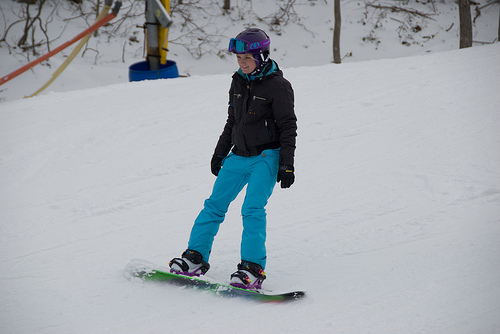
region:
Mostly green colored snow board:
[125, 258, 305, 299]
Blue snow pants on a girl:
[188, 142, 281, 269]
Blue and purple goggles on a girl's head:
[227, 35, 272, 55]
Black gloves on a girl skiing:
[211, 153, 295, 189]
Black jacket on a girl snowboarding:
[215, 63, 298, 168]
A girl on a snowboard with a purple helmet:
[169, 27, 298, 287]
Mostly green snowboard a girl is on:
[128, 263, 305, 300]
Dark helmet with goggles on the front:
[232, 28, 271, 60]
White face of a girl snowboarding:
[234, 52, 257, 76]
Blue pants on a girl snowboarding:
[188, 136, 281, 272]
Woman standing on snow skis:
[130, 25, 307, 307]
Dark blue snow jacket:
[206, 62, 296, 187]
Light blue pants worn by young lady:
[180, 145, 280, 260]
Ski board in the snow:
[125, 260, 305, 300]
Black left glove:
[275, 160, 296, 185]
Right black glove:
[205, 150, 221, 171]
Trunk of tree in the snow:
[455, 0, 475, 50]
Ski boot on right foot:
[168, 246, 208, 276]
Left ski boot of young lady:
[225, 256, 270, 291]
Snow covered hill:
[4, 39, 497, 330]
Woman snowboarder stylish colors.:
[135, 17, 330, 322]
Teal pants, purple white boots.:
[172, 135, 279, 290]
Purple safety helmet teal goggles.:
[219, 24, 287, 88]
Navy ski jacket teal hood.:
[203, 56, 305, 156]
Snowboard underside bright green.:
[115, 264, 324, 302]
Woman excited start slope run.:
[213, 16, 296, 96]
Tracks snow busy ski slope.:
[9, 143, 492, 313]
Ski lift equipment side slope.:
[117, 1, 195, 93]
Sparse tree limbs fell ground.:
[182, 3, 482, 48]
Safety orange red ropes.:
[3, 5, 139, 109]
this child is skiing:
[14, 14, 429, 294]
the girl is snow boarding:
[172, 26, 317, 311]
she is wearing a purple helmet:
[217, 24, 283, 84]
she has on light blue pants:
[170, 145, 295, 288]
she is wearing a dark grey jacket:
[208, 68, 312, 190]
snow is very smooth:
[31, 81, 473, 321]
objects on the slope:
[5, 8, 197, 94]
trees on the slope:
[312, 4, 484, 72]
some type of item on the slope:
[120, 0, 190, 85]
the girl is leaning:
[110, 37, 367, 291]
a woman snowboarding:
[133, 25, 390, 328]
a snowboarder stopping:
[105, 7, 428, 327]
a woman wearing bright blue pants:
[123, 13, 431, 327]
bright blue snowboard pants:
[186, 136, 306, 310]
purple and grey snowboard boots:
[156, 243, 287, 291]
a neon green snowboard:
[129, 262, 314, 314]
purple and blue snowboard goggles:
[218, 38, 286, 52]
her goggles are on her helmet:
[214, 30, 299, 89]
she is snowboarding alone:
[168, 12, 353, 326]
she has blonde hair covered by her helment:
[228, 13, 293, 79]